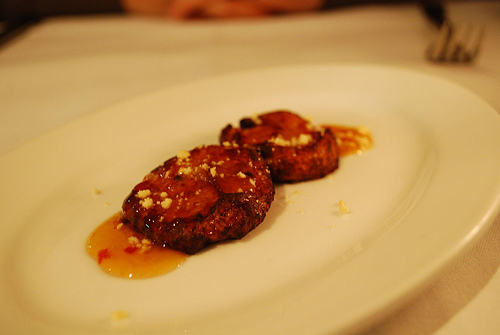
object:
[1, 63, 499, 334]
plate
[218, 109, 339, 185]
steak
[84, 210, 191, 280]
sauce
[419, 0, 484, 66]
fork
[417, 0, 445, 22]
handle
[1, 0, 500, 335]
table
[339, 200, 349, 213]
piece of cheese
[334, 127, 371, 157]
cheese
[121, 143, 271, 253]
chili flakes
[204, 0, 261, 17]
hands